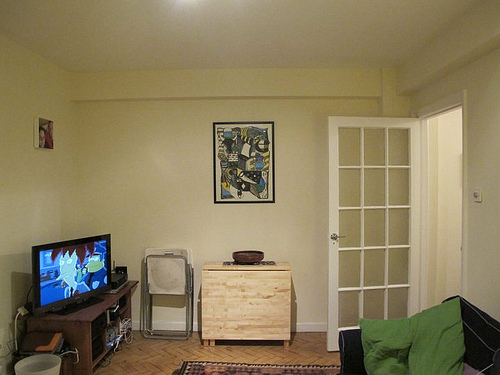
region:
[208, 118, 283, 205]
picture hanging on wall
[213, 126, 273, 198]
black frame on picture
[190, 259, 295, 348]
brown table in room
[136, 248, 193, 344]
folding chair on wall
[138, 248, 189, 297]
white bottom of chair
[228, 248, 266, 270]
brown bowl on table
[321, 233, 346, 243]
silver handle on door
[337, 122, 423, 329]
windows on front of door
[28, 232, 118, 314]
small black tv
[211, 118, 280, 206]
framed art work affixed to wall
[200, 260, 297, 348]
blonde chest against wall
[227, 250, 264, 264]
decorative bowl on top of chest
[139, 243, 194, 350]
white folding chair against wall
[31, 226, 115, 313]
flat screen television on stand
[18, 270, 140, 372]
brown wooden television stand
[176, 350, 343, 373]
area rug on living room floor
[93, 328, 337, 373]
wood-grained pattern floor tile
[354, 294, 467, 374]
green decorative pillow on sofa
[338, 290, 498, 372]
black sofa with white trim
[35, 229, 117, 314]
LARGE FLAT SCREENED TV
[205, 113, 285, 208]
FRAMED PICTURE ON WALL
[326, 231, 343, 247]
HANDLE ON OPEN DOOR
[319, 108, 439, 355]
OPEN GLASS PANED DOOR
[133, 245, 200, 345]
FOLDING CHAIR STACKED AGAINST WALL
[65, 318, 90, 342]
PART OF WOODEN BROWN TV STAND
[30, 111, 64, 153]
SMALL PICTURE PANE ON WALL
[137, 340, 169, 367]
PART OF BROWN WOOD FLOOR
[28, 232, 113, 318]
Episode of the Simpsons Television show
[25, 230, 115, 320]
Black flat screen television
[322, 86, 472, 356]
Open glass panel door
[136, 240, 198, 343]
Folded up white chair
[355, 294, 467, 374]
Bright green pillow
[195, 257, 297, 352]
Drop side leaf table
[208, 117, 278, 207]
Black framed art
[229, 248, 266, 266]
Brown decorative bowl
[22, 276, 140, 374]
Small brown entertainment center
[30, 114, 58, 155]
Photograph of two people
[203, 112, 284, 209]
a picture hanging on the wall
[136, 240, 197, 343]
folding chairs against the wall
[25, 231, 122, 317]
The Simpsons are on TV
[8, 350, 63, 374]
wastebasket beside the TV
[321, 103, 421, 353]
French door for this room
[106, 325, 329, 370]
parquet floor in this room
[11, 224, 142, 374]
a little entertainment center in this room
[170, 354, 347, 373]
a floor rug on the wooden floor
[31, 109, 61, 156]
a small picture hanging on the wall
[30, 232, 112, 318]
A TV on a stand in a living room.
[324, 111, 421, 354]
A large white door with many panes of glass.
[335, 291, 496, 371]
A couch with a pillow.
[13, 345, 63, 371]
A bucket near a TV.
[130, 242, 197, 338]
A group of fold up chairs against a wall.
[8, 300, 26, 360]
A wire behind a TV.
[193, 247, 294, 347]
A dress with a bowl on top.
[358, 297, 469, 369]
A green blanket on a couch.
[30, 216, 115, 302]
a tv on the stand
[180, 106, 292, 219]
a picture on the wall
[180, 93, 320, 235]
a wall with a picture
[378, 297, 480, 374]
a pillow on the couch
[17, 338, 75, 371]
a white garbage can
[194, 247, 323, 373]
a wooden dresser